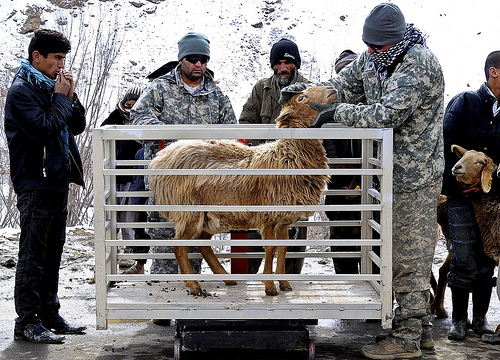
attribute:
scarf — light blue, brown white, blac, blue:
[9, 60, 72, 169]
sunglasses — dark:
[185, 54, 210, 65]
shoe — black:
[14, 322, 66, 344]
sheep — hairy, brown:
[449, 143, 497, 192]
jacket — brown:
[239, 68, 314, 147]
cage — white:
[96, 123, 394, 330]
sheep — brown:
[143, 83, 341, 298]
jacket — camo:
[293, 43, 446, 195]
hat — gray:
[363, 2, 406, 44]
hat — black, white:
[118, 86, 144, 103]